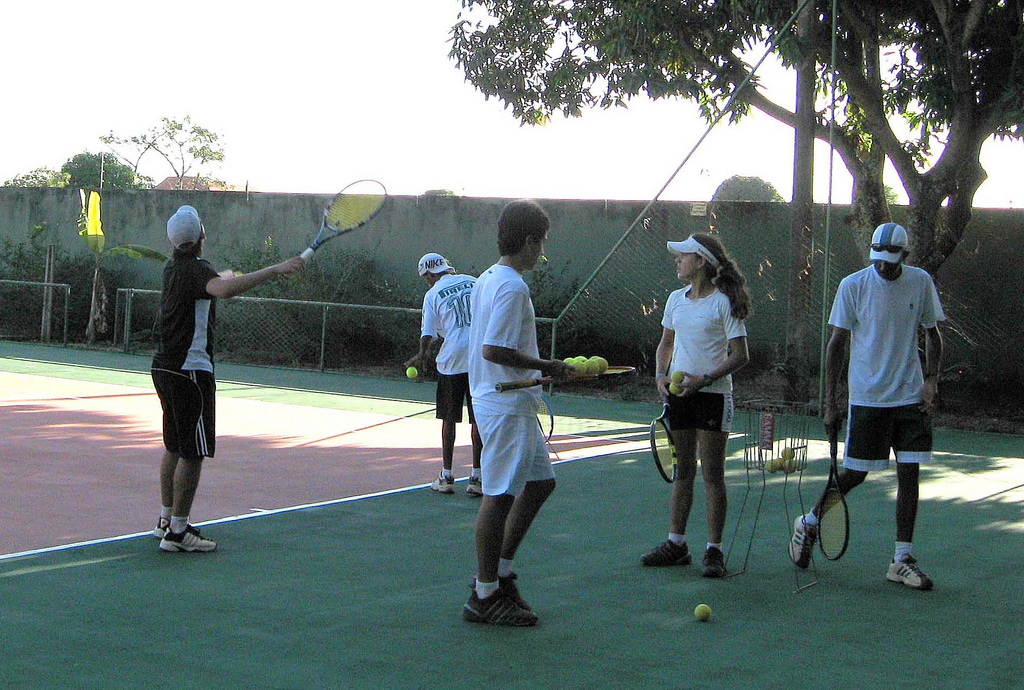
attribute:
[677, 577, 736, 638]
tennis ball — yellow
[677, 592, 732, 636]
tennis ball — yellow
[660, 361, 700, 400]
tennis ball — yellow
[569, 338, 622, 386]
tennis ball — yellow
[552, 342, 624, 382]
tennis ball — yellow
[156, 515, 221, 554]
foot — persons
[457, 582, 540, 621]
foot — persons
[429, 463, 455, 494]
foot — persons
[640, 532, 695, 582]
foot — persons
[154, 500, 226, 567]
foot — persons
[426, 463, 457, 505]
foot — persons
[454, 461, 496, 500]
foot — persons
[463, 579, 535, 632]
foot — persons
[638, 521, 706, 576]
foot — persons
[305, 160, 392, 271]
racket — tennis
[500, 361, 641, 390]
racket — tennis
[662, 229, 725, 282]
visor — sun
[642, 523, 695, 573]
shoe — tennis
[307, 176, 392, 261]
racket — tennis, grey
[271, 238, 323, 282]
handle — white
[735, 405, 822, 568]
bin — wire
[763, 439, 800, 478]
balls — tennis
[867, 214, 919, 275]
cap — blue, white, ball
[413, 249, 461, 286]
cap — ball, black, white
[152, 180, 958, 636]
people — several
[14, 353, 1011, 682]
court — outdoor, tennis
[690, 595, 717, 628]
ball — tennis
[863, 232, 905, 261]
sunglasses — man's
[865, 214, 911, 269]
hat — his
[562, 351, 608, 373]
balls — several, tennis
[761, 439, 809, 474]
balls — tennis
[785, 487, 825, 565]
leg — long, metal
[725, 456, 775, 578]
leg — long, metal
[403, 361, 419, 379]
ball — tennis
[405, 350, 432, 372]
hand — man's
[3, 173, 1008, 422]
wall — cement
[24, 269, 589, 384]
fence — chain link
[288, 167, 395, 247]
racket — tennis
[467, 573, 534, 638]
foot — persons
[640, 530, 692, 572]
foot — persons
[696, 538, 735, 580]
foot — persons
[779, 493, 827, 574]
foot — persons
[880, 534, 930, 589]
foot — persons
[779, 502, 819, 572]
foot — persons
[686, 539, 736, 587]
foot — persons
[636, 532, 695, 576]
foot — persons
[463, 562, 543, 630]
foot — persons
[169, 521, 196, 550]
foot — persons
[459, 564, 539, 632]
foot — persons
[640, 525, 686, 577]
foot — persons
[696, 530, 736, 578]
foot — persons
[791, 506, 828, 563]
foot — persons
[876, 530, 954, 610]
foot — persons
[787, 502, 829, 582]
foot — persons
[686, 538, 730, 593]
foot — persons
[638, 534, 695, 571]
foot — persons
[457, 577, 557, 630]
foot — persons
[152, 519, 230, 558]
foot — persons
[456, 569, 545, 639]
foot — persons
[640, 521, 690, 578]
foot — persons